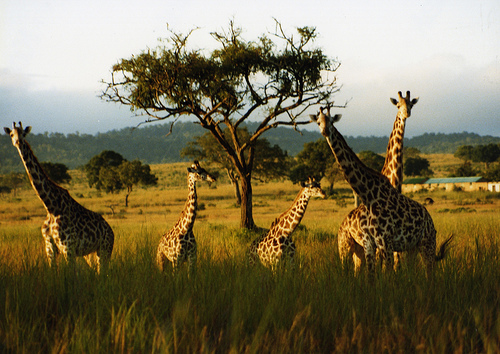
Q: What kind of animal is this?
A: Giraffe.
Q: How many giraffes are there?
A: Five.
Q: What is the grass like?
A: Tall.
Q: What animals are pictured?
A: Giraffe.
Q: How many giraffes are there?
A: Five.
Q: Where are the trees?
A: Behind the giraffes.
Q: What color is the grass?
A: Green.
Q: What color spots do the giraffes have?
A: Brown.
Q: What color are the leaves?
A: Green.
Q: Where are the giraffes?
A: In a field.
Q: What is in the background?
A: Hills.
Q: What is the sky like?
A: Overcast.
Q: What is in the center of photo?
A: A tree.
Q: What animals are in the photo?
A: Giraffes.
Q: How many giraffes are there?
A: 5.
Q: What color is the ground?
A: Brown.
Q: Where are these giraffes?
A: In a field.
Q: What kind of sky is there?
A: Cloudy.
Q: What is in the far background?
A: Trees.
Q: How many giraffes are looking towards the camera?
A: 3.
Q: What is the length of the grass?
A: It's tall.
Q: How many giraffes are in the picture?
A: Five.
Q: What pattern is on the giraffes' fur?
A: Spots.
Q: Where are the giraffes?
A: In a field.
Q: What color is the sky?
A: Gray.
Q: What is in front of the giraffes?
A: Grass.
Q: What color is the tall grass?
A: Green.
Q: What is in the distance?
A: Trees.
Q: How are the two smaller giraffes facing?
A: To the right.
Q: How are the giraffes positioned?
A: Standing.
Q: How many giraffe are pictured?
A: Five.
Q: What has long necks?
A: The giraffe.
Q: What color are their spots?
A: Brown.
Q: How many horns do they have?
A: 2.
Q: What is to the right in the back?
A: A house.